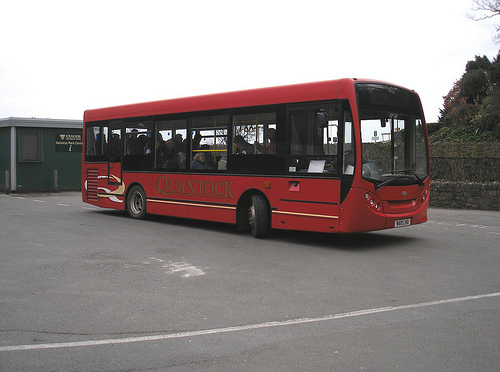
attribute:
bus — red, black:
[82, 79, 429, 236]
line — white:
[1, 291, 499, 354]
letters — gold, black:
[157, 175, 235, 199]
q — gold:
[156, 175, 169, 198]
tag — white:
[393, 219, 412, 229]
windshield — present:
[355, 84, 430, 185]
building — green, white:
[0, 117, 84, 194]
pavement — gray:
[0, 191, 499, 372]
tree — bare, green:
[441, 53, 499, 135]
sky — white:
[3, 0, 500, 125]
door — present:
[107, 121, 123, 185]